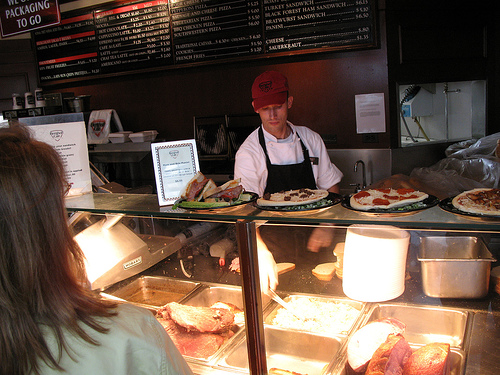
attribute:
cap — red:
[217, 69, 293, 145]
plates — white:
[326, 209, 398, 325]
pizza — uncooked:
[346, 164, 438, 234]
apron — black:
[252, 153, 331, 259]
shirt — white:
[220, 125, 342, 209]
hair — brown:
[5, 130, 67, 359]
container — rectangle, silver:
[416, 226, 496, 299]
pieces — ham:
[348, 321, 473, 372]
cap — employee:
[241, 69, 288, 112]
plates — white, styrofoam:
[340, 218, 410, 299]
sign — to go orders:
[3, 2, 62, 40]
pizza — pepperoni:
[348, 180, 428, 210]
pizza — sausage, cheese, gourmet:
[256, 183, 334, 204]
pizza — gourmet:
[348, 183, 430, 213]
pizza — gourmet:
[449, 183, 498, 223]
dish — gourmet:
[174, 170, 253, 208]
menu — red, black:
[8, 2, 391, 102]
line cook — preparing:
[225, 66, 345, 267]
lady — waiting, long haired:
[0, 123, 185, 373]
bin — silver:
[414, 226, 497, 302]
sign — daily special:
[144, 130, 209, 204]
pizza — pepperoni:
[344, 182, 423, 212]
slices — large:
[369, 193, 389, 206]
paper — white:
[148, 133, 202, 207]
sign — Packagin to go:
[4, 0, 56, 36]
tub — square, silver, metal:
[415, 234, 496, 299]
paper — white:
[352, 90, 387, 137]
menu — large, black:
[0, 6, 384, 54]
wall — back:
[40, 27, 392, 106]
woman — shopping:
[2, 123, 193, 371]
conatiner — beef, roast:
[154, 300, 241, 360]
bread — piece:
[309, 254, 341, 280]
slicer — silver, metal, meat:
[69, 213, 176, 285]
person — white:
[244, 68, 338, 208]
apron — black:
[259, 136, 313, 202]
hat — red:
[250, 66, 286, 111]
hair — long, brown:
[7, 176, 100, 333]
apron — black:
[245, 137, 322, 186]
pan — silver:
[384, 306, 439, 329]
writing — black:
[159, 143, 197, 193]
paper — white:
[149, 137, 206, 209]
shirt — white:
[229, 114, 346, 204]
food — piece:
[409, 341, 448, 371]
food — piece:
[367, 329, 411, 373]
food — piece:
[365, 329, 408, 363]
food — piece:
[164, 298, 234, 337]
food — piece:
[183, 173, 205, 203]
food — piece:
[194, 172, 222, 202]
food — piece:
[216, 176, 247, 202]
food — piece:
[349, 180, 373, 207]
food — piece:
[369, 188, 391, 210]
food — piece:
[379, 184, 426, 206]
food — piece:
[261, 186, 317, 207]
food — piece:
[181, 177, 204, 204]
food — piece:
[210, 180, 243, 206]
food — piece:
[213, 179, 240, 201]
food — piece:
[457, 182, 491, 216]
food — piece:
[369, 192, 391, 212]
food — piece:
[383, 186, 402, 203]